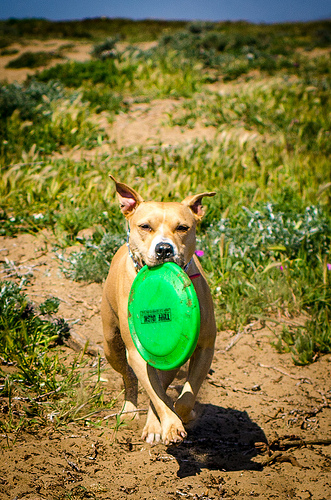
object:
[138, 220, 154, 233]
open eye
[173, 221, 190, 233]
open eye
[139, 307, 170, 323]
writing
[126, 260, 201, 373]
frisbee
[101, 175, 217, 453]
dog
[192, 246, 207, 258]
flower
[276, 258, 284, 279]
flower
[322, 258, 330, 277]
flower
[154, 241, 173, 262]
nose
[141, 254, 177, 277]
mouth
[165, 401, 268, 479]
shadow